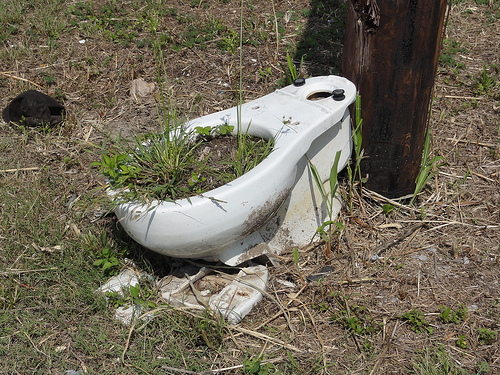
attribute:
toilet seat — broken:
[92, 247, 270, 327]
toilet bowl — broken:
[85, 68, 364, 328]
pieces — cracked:
[92, 257, 277, 332]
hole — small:
[310, 84, 338, 109]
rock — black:
[1, 89, 68, 129]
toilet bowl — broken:
[102, 72, 364, 265]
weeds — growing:
[99, 124, 266, 210]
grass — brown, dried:
[0, 0, 498, 374]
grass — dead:
[7, 276, 84, 363]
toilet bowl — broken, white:
[102, 71, 362, 290]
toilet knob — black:
[271, 69, 306, 89]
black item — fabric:
[1, 89, 67, 127]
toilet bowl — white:
[109, 72, 369, 279]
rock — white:
[126, 75, 161, 107]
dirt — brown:
[4, 3, 498, 373]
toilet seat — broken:
[105, 72, 357, 267]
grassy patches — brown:
[335, 301, 472, 336]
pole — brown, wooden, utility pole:
[339, 0, 451, 207]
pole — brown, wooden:
[330, 4, 458, 206]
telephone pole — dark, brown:
[357, 6, 456, 183]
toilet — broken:
[100, 39, 387, 296]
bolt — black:
[291, 76, 306, 87]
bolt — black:
[330, 89, 345, 101]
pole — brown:
[301, 5, 437, 193]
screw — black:
[328, 87, 348, 104]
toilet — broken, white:
[103, 70, 362, 262]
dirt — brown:
[245, 196, 292, 250]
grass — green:
[330, 273, 484, 353]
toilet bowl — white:
[97, 67, 355, 274]